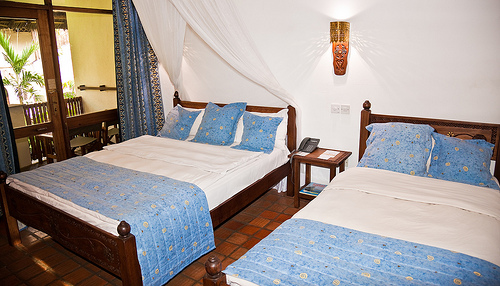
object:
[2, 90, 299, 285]
bed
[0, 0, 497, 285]
room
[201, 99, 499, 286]
bed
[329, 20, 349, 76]
light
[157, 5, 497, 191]
wall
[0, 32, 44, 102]
tree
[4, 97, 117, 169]
patio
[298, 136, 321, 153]
phone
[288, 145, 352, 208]
nightstand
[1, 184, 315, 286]
floor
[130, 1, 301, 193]
net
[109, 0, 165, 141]
curtains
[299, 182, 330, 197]
magazine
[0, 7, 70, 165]
door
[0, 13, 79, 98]
outside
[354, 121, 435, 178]
pillows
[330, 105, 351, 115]
switch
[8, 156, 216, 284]
bedspread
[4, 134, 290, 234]
sheet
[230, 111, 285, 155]
pillows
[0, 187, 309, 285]
tile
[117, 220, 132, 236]
knob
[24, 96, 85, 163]
railing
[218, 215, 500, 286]
bedspread